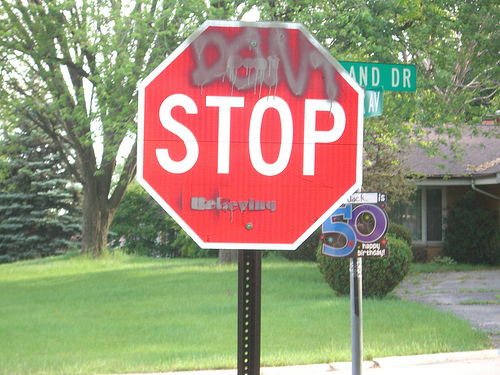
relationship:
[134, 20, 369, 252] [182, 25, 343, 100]
sign has graffiti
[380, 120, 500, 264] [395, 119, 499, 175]
house has roof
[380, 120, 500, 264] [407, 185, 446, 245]
house has window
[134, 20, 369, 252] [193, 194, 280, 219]
sign has graffiti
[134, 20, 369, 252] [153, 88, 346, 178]
sign has letters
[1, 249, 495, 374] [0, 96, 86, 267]
grass has tree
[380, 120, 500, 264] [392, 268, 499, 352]
house has driveway